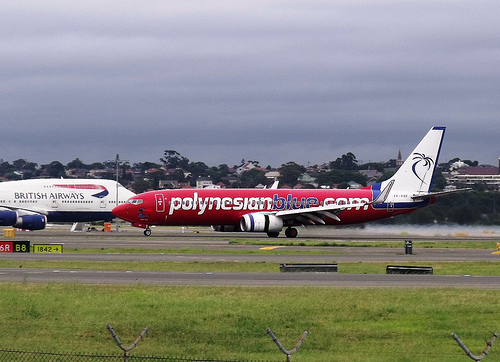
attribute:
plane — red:
[111, 125, 471, 236]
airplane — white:
[104, 109, 455, 258]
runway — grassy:
[0, 265, 497, 292]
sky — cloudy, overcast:
[14, 14, 497, 156]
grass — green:
[4, 272, 498, 356]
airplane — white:
[105, 119, 474, 259]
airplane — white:
[2, 158, 143, 242]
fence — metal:
[2, 323, 499, 360]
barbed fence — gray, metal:
[5, 303, 493, 359]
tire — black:
[285, 228, 298, 238]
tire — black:
[267, 230, 280, 240]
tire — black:
[143, 226, 151, 234]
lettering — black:
[14, 189, 86, 199]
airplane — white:
[2, 176, 137, 228]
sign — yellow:
[33, 241, 63, 252]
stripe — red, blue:
[370, 182, 425, 214]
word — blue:
[269, 192, 319, 212]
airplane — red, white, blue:
[108, 122, 473, 240]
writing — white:
[166, 191, 273, 216]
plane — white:
[111, 150, 469, 252]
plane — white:
[104, 153, 462, 268]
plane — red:
[110, 123, 472, 222]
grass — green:
[1, 280, 498, 358]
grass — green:
[1, 257, 498, 275]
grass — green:
[61, 246, 351, 254]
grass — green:
[230, 236, 498, 250]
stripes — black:
[241, 208, 256, 234]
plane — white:
[3, 170, 114, 208]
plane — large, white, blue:
[3, 170, 138, 245]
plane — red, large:
[111, 174, 468, 246]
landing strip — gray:
[1, 204, 473, 254]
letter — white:
[168, 195, 181, 215]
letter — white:
[180, 197, 192, 209]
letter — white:
[195, 195, 208, 215]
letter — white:
[207, 195, 221, 210]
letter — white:
[221, 195, 233, 210]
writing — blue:
[162, 196, 276, 223]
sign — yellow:
[32, 238, 69, 255]